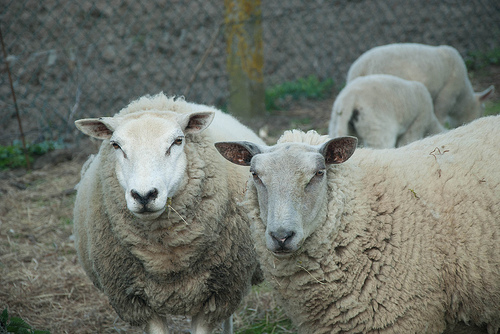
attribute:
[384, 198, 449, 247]
sheep — standing, grazing, ready, close, feeding, sheared, adult, white, four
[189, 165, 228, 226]
wool — white, thick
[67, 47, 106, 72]
ground — muddy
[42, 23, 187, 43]
fence — chain link